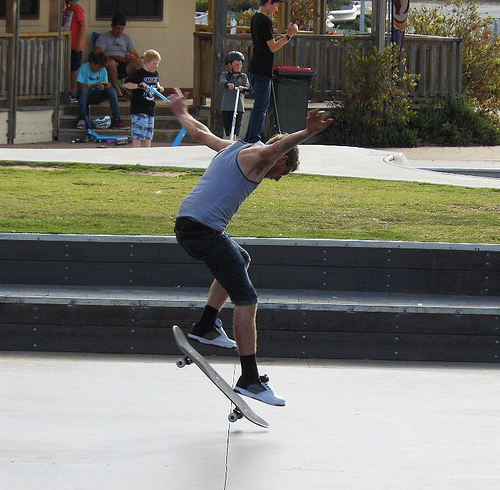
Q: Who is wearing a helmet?
A: Boy background.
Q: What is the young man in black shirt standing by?
A: Garbage can.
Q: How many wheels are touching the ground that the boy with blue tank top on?
A: None.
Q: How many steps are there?
A: Five.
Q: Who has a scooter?
A: Boy background with helmet on.